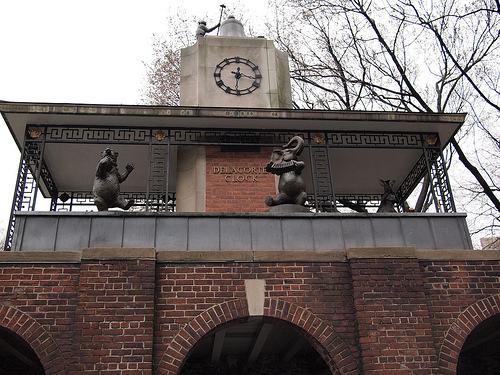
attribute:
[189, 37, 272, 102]
clock — at 3:30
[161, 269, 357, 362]
archway — brick, red brick, entry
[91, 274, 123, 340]
wall — missing a brick, brick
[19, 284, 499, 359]
building — sectioned, brick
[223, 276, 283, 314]
capstone — white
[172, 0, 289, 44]
statue — elephant, bronze elephant, playing music, on top of building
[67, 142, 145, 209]
bear statue — small, dark bronze, dancing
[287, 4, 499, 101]
tree — bare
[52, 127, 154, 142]
design — black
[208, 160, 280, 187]
sign — delacorta clock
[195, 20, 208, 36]
monkey statue — ringing bell